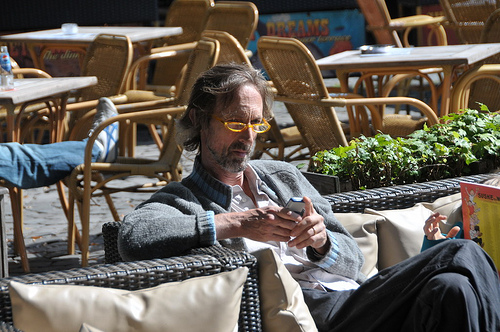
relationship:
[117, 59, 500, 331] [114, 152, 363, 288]
man wearing sweater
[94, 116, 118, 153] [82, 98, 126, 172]
stripes are attached to sneaker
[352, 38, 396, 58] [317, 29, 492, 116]
ashtray on top of table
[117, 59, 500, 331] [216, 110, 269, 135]
man wearing eyeglasses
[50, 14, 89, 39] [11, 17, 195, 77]
holder on top of table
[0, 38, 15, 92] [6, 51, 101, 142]
bottle on top of table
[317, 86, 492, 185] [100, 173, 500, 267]
bush behind furniture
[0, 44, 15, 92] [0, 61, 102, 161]
bottle on top of table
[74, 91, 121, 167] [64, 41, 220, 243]
foot on top of chair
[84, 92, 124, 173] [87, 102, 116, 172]
sneaker attached to foot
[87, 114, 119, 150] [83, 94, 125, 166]
designs are attached to sneaker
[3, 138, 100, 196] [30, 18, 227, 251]
leg on top of chair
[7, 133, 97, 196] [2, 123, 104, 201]
jeans are covering leg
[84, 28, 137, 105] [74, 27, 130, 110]
backrest attached to chair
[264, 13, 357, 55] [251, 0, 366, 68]
writing attached to poster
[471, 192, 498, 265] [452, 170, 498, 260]
paper in front of book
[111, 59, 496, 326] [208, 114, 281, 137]
man wearing glasses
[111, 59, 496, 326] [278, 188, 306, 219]
man looking at cellphone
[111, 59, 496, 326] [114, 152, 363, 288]
man wearing sweater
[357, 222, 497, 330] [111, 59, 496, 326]
legs of man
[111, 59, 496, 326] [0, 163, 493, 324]
man sitting on furniture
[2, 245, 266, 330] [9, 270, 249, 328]
chair with pillow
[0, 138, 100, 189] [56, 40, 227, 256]
leg propped up on chair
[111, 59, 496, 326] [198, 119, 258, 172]
man has beard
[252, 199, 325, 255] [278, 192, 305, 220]
hands holding cellphone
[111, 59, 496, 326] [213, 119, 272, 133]
man wearing eyeglasses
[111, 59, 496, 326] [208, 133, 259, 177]
man has beard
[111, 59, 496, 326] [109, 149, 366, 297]
man wearing sweater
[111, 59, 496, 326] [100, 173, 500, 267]
man sitting on furniture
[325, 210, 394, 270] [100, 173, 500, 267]
pillow on furniture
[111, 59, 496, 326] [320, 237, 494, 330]
man wearing pants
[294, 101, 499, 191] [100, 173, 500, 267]
bush behind furniture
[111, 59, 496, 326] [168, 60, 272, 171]
man has hair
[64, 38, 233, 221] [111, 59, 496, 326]
chair behind man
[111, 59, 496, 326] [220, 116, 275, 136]
man wearing glasses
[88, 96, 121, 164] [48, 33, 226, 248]
foot resting on chair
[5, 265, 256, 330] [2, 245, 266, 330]
pillow on chair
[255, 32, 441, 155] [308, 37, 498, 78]
chair near table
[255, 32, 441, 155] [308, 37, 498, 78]
chair at table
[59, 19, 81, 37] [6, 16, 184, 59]
jar on table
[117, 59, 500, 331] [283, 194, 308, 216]
man using device